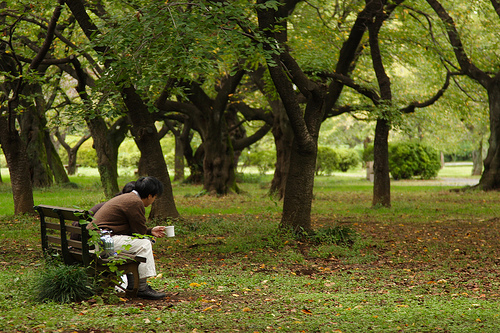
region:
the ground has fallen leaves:
[222, 165, 472, 301]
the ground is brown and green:
[265, 238, 421, 296]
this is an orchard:
[148, 51, 377, 173]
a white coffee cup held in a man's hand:
[164, 224, 174, 239]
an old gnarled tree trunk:
[199, 110, 239, 201]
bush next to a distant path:
[391, 140, 444, 177]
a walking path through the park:
[337, 176, 491, 186]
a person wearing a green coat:
[361, 143, 375, 160]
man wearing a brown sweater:
[94, 189, 149, 234]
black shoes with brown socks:
[123, 276, 167, 299]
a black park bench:
[38, 200, 148, 291]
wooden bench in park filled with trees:
[7, 8, 492, 324]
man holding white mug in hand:
[127, 171, 179, 303]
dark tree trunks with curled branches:
[7, 9, 496, 240]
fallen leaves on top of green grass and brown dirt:
[3, 171, 494, 326]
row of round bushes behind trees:
[37, 91, 484, 180]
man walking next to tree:
[357, 127, 397, 184]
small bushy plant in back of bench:
[29, 200, 147, 309]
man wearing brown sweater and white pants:
[87, 177, 171, 299]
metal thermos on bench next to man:
[88, 201, 143, 268]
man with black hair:
[129, 176, 161, 206]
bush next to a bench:
[26, 254, 91, 305]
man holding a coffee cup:
[157, 220, 178, 238]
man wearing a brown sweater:
[82, 190, 148, 231]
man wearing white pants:
[104, 231, 164, 277]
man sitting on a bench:
[87, 177, 189, 294]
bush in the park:
[381, 133, 446, 183]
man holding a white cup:
[156, 216, 185, 243]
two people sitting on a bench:
[29, 189, 178, 293]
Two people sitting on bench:
[33, 175, 176, 301]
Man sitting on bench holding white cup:
[86, 174, 177, 299]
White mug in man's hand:
[153, 223, 176, 238]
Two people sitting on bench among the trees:
[3, 5, 498, 329]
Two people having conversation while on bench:
[30, 176, 175, 301]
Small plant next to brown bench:
[73, 205, 153, 305]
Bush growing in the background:
[388, 140, 442, 180]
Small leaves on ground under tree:
[180, 210, 499, 330]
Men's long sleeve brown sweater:
[91, 189, 152, 237]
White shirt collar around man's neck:
[129, 188, 140, 196]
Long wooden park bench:
[36, 205, 147, 294]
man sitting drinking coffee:
[89, 176, 174, 303]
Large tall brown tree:
[239, 3, 386, 243]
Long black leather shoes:
[126, 286, 166, 300]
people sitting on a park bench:
[40, 178, 180, 300]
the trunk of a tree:
[282, 156, 317, 231]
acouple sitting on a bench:
[28, 166, 182, 307]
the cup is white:
[161, 219, 177, 239]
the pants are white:
[86, 230, 156, 280]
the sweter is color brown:
[88, 191, 154, 237]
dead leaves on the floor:
[349, 212, 493, 295]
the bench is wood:
[26, 198, 105, 293]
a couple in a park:
[3, 5, 493, 332]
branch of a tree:
[401, 68, 458, 124]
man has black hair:
[120, 168, 174, 220]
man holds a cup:
[83, 171, 180, 301]